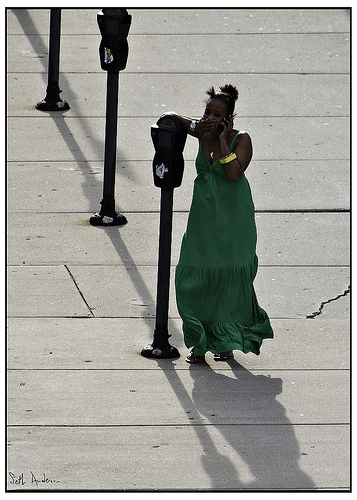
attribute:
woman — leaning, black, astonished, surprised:
[172, 81, 275, 366]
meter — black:
[93, 6, 133, 231]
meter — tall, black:
[146, 116, 188, 363]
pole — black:
[36, 6, 72, 113]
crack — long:
[305, 281, 349, 328]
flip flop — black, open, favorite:
[184, 347, 203, 362]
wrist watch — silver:
[192, 119, 198, 135]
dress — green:
[173, 131, 272, 357]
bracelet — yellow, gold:
[214, 150, 240, 166]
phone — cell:
[217, 114, 232, 128]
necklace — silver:
[208, 150, 216, 162]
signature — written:
[10, 472, 63, 488]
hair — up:
[206, 83, 242, 110]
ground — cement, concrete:
[6, 14, 352, 494]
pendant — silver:
[208, 151, 213, 160]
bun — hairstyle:
[219, 82, 241, 94]